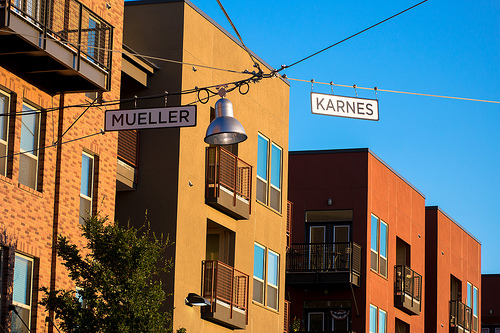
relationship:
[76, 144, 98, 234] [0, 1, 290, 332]
window on building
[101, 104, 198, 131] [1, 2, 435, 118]
sign on wire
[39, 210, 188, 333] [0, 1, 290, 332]
tree near building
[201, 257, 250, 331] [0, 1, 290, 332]
balcony on building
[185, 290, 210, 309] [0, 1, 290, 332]
light on building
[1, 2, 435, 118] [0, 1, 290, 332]
wire by building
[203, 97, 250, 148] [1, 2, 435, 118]
lamp on wire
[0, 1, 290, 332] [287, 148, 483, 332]
building and structure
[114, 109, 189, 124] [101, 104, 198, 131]
writing on sign